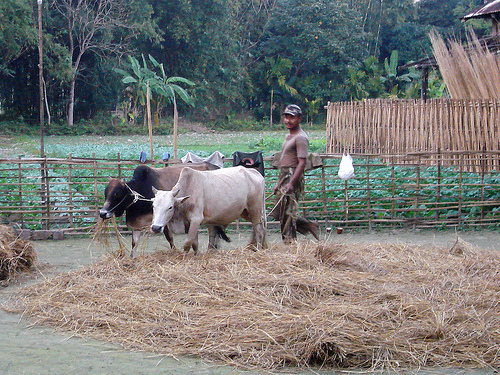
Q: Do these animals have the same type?
A: Yes, all the animals are cows.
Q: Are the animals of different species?
A: No, all the animals are cows.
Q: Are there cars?
A: No, there are no cars.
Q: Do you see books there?
A: No, there are no books.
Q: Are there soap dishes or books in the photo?
A: No, there are no books or soap dishes.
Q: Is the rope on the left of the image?
A: Yes, the rope is on the left of the image.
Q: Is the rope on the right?
A: No, the rope is on the left of the image.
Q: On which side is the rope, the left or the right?
A: The rope is on the left of the image.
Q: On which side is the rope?
A: The rope is on the left of the image.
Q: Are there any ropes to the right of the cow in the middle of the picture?
A: No, the rope is to the left of the cow.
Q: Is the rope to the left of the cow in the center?
A: Yes, the rope is to the left of the cow.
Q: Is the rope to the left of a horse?
A: No, the rope is to the left of the cow.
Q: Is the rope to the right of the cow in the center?
A: No, the rope is to the left of the cow.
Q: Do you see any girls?
A: No, there are no girls.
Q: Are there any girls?
A: No, there are no girls.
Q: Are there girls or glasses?
A: No, there are no girls or glasses.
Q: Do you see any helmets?
A: No, there are no helmets.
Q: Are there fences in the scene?
A: Yes, there is a fence.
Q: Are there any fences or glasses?
A: Yes, there is a fence.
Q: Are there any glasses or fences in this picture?
A: Yes, there is a fence.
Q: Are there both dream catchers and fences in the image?
A: No, there is a fence but no dream catchers.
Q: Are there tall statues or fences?
A: Yes, there is a tall fence.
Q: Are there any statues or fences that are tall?
A: Yes, the fence is tall.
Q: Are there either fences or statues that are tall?
A: Yes, the fence is tall.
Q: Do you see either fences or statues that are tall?
A: Yes, the fence is tall.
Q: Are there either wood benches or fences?
A: Yes, there is a wood fence.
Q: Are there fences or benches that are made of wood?
A: Yes, the fence is made of wood.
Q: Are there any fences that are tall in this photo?
A: Yes, there is a tall fence.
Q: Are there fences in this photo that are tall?
A: Yes, there is a fence that is tall.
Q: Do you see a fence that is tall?
A: Yes, there is a fence that is tall.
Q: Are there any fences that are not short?
A: Yes, there is a tall fence.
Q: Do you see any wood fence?
A: Yes, there is a wood fence.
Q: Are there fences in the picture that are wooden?
A: Yes, there is a fence that is wooden.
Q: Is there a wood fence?
A: Yes, there is a fence that is made of wood.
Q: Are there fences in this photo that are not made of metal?
A: Yes, there is a fence that is made of wood.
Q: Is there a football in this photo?
A: No, there are no footballs.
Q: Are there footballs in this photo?
A: No, there are no footballs.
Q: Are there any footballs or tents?
A: No, there are no footballs or tents.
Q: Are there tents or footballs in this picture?
A: No, there are no footballs or tents.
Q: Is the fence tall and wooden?
A: Yes, the fence is tall and wooden.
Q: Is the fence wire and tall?
A: No, the fence is tall but wooden.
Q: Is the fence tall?
A: Yes, the fence is tall.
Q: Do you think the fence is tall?
A: Yes, the fence is tall.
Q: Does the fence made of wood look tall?
A: Yes, the fence is tall.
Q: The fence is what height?
A: The fence is tall.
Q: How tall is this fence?
A: The fence is tall.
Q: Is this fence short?
A: No, the fence is tall.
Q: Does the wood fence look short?
A: No, the fence is tall.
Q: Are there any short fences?
A: No, there is a fence but it is tall.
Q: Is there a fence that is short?
A: No, there is a fence but it is tall.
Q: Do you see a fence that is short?
A: No, there is a fence but it is tall.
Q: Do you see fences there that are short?
A: No, there is a fence but it is tall.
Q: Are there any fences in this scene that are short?
A: No, there is a fence but it is tall.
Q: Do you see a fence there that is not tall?
A: No, there is a fence but it is tall.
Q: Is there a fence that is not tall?
A: No, there is a fence but it is tall.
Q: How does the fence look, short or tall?
A: The fence is tall.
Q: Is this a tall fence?
A: Yes, this is a tall fence.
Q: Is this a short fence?
A: No, this is a tall fence.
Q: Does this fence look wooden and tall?
A: Yes, the fence is wooden and tall.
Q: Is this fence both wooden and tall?
A: Yes, the fence is wooden and tall.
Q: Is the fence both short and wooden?
A: No, the fence is wooden but tall.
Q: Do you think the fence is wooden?
A: Yes, the fence is wooden.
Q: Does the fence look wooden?
A: Yes, the fence is wooden.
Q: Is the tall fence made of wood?
A: Yes, the fence is made of wood.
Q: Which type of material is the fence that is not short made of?
A: The fence is made of wood.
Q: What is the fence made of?
A: The fence is made of wood.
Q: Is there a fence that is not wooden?
A: No, there is a fence but it is wooden.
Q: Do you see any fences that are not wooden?
A: No, there is a fence but it is wooden.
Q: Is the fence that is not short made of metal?
A: No, the fence is made of wood.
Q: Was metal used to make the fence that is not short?
A: No, the fence is made of wood.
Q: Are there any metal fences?
A: No, there is a fence but it is made of wood.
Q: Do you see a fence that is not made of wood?
A: No, there is a fence but it is made of wood.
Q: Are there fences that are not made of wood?
A: No, there is a fence but it is made of wood.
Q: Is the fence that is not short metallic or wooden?
A: The fence is wooden.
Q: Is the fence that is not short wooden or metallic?
A: The fence is wooden.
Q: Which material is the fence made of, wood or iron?
A: The fence is made of wood.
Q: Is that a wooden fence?
A: Yes, that is a wooden fence.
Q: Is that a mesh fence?
A: No, that is a wooden fence.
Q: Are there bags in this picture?
A: Yes, there is a bag.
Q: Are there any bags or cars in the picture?
A: Yes, there is a bag.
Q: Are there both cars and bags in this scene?
A: No, there is a bag but no cars.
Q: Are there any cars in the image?
A: No, there are no cars.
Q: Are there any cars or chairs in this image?
A: No, there are no cars or chairs.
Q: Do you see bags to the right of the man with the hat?
A: Yes, there is a bag to the right of the man.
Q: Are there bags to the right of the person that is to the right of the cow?
A: Yes, there is a bag to the right of the man.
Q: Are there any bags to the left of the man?
A: No, the bag is to the right of the man.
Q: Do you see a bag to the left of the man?
A: No, the bag is to the right of the man.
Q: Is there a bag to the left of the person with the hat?
A: No, the bag is to the right of the man.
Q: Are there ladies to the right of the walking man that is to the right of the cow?
A: No, there is a bag to the right of the man.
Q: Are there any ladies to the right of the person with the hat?
A: No, there is a bag to the right of the man.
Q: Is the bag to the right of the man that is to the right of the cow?
A: Yes, the bag is to the right of the man.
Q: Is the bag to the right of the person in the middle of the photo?
A: Yes, the bag is to the right of the man.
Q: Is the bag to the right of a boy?
A: No, the bag is to the right of the man.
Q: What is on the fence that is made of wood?
A: The bag is on the fence.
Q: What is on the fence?
A: The bag is on the fence.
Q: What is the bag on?
A: The bag is on the fence.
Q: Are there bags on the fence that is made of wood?
A: Yes, there is a bag on the fence.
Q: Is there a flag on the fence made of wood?
A: No, there is a bag on the fence.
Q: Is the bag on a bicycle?
A: No, the bag is on a fence.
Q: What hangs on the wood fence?
A: The bag hangs on the fence.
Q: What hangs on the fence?
A: The bag hangs on the fence.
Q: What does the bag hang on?
A: The bag hangs on the fence.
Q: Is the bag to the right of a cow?
A: Yes, the bag is to the right of a cow.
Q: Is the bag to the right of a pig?
A: No, the bag is to the right of a cow.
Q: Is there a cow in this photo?
A: Yes, there is a cow.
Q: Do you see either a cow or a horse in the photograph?
A: Yes, there is a cow.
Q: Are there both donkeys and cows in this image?
A: No, there is a cow but no donkeys.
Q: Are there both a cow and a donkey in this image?
A: No, there is a cow but no donkeys.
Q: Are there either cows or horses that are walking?
A: Yes, the cow is walking.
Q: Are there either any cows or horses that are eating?
A: Yes, the cow is eating.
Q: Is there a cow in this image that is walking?
A: Yes, there is a cow that is walking.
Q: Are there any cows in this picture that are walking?
A: Yes, there is a cow that is walking.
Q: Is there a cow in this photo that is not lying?
A: Yes, there is a cow that is walking.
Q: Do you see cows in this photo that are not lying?
A: Yes, there is a cow that is walking .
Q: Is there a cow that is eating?
A: Yes, there is a cow that is eating.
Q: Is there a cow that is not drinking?
A: Yes, there is a cow that is eating.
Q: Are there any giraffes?
A: No, there are no giraffes.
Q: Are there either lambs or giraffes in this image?
A: No, there are no giraffes or lambs.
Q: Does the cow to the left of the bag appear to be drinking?
A: No, the cow is eating.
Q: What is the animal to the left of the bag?
A: The animal is a cow.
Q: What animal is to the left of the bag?
A: The animal is a cow.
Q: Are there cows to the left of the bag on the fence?
A: Yes, there is a cow to the left of the bag.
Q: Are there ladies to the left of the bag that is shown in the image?
A: No, there is a cow to the left of the bag.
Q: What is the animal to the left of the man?
A: The animal is a cow.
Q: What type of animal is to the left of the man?
A: The animal is a cow.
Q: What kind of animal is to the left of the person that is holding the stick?
A: The animal is a cow.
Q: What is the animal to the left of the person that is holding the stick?
A: The animal is a cow.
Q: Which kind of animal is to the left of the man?
A: The animal is a cow.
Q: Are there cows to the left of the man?
A: Yes, there is a cow to the left of the man.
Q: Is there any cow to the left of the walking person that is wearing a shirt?
A: Yes, there is a cow to the left of the man.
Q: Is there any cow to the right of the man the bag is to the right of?
A: No, the cow is to the left of the man.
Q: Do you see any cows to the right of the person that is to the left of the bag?
A: No, the cow is to the left of the man.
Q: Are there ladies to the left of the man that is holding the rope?
A: No, there is a cow to the left of the man.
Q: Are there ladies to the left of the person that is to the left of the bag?
A: No, there is a cow to the left of the man.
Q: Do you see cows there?
A: Yes, there is a cow.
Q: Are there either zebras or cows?
A: Yes, there is a cow.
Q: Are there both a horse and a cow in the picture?
A: No, there is a cow but no horses.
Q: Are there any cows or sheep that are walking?
A: Yes, the cow is walking.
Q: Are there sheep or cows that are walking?
A: Yes, the cow is walking.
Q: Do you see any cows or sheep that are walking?
A: Yes, the cow is walking.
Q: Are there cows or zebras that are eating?
A: Yes, the cow is eating.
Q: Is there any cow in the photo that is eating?
A: Yes, there is a cow that is eating.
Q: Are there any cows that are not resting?
A: Yes, there is a cow that is eating.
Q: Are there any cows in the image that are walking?
A: Yes, there is a cow that is walking.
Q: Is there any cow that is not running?
A: Yes, there is a cow that is walking.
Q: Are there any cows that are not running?
A: Yes, there is a cow that is walking.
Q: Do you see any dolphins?
A: No, there are no dolphins.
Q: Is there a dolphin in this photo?
A: No, there are no dolphins.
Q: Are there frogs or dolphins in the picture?
A: No, there are no dolphins or frogs.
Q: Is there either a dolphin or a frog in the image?
A: No, there are no dolphins or frogs.